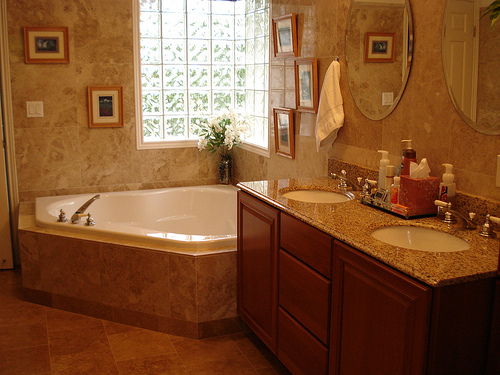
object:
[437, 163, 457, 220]
bottle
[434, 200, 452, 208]
knob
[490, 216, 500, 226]
knob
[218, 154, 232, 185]
vase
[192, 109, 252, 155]
flowers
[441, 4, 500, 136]
reflection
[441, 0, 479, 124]
door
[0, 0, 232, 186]
wall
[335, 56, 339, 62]
hook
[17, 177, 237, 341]
bath tub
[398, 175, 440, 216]
box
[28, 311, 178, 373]
tiles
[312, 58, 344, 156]
towel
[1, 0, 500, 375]
bathroom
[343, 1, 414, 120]
mirrors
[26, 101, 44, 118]
light switches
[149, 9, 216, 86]
glass blocks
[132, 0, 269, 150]
bathroom window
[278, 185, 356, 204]
sink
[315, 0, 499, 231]
wall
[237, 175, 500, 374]
counter